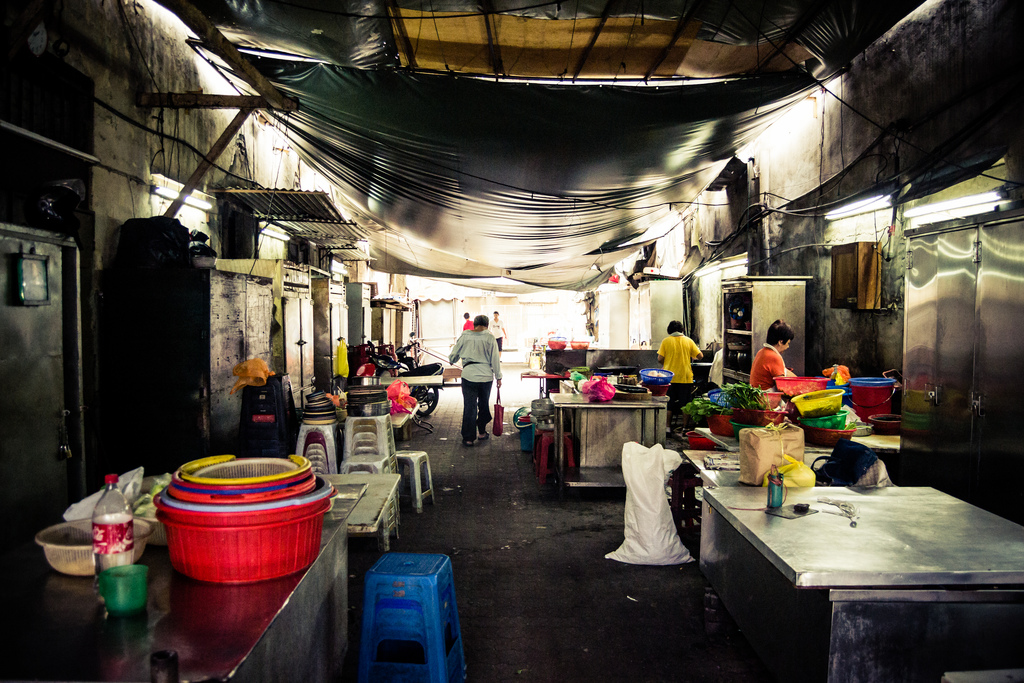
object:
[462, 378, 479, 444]
legs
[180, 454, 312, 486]
bowls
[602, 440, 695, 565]
bag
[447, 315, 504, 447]
person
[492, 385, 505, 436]
bag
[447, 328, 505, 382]
shirt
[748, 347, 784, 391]
shirt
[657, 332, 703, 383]
shirt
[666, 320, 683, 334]
hair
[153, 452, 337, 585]
plastic bowls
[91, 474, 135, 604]
bottle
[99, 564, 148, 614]
cup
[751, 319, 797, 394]
woman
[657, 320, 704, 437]
person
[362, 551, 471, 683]
stool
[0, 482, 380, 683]
table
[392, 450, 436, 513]
stool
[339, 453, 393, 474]
stool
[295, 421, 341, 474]
stool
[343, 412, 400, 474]
stool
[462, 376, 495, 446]
jeans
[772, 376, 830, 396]
bowl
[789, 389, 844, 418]
bowl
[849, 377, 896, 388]
bowl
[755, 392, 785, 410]
bowl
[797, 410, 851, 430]
bowl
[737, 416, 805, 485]
package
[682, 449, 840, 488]
table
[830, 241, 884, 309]
cabinet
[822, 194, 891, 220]
light